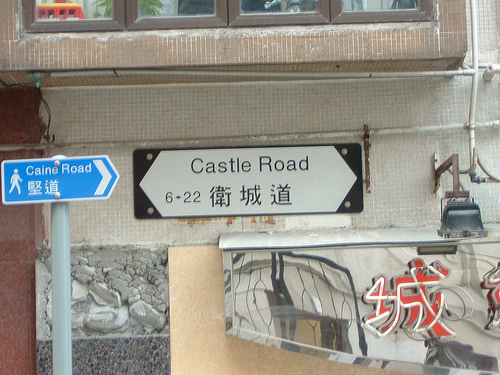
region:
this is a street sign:
[0, 153, 127, 373]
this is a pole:
[40, 211, 80, 371]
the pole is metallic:
[48, 209, 80, 364]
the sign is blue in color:
[63, 177, 82, 188]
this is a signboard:
[128, 138, 368, 222]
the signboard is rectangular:
[126, 138, 364, 226]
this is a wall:
[222, 87, 348, 124]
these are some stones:
[98, 273, 163, 328]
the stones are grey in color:
[86, 274, 163, 329]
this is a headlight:
[432, 194, 487, 249]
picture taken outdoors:
[32, 35, 493, 325]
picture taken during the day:
[35, 28, 486, 268]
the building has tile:
[108, 61, 363, 116]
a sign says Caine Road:
[15, 145, 157, 221]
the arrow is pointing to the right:
[10, 158, 227, 285]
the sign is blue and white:
[18, 146, 161, 223]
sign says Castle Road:
[126, 133, 456, 217]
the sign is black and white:
[128, 121, 389, 248]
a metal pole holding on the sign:
[16, 142, 67, 362]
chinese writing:
[322, 224, 487, 356]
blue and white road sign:
[3, 158, 120, 201]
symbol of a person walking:
[7, 169, 26, 195]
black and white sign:
[132, 145, 366, 210]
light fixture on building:
[428, 154, 488, 243]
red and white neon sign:
[361, 259, 461, 343]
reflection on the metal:
[222, 248, 378, 358]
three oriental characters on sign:
[207, 183, 299, 207]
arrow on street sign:
[91, 158, 112, 199]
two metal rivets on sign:
[50, 158, 66, 200]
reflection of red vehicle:
[33, 3, 87, 23]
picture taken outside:
[118, 156, 385, 340]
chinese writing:
[176, 169, 482, 329]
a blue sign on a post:
[26, 148, 137, 374]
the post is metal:
[45, 197, 105, 361]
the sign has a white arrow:
[22, 148, 162, 218]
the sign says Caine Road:
[16, 144, 156, 238]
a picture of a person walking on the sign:
[11, 156, 25, 205]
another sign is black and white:
[131, 133, 433, 274]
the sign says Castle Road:
[111, 134, 432, 305]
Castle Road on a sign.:
[170, 150, 325, 180]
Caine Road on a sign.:
[18, 160, 103, 183]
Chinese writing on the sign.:
[207, 177, 307, 215]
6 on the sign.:
[155, 187, 179, 213]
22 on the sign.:
[180, 186, 207, 210]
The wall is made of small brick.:
[59, 63, 369, 133]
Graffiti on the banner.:
[351, 261, 498, 345]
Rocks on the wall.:
[41, 248, 171, 339]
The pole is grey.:
[43, 202, 89, 373]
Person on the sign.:
[5, 155, 27, 207]